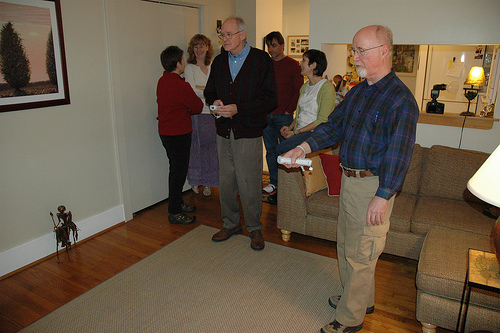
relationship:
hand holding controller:
[278, 144, 310, 174] [275, 158, 312, 168]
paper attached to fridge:
[445, 58, 465, 80] [421, 48, 483, 113]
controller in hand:
[277, 156, 314, 171] [273, 146, 308, 171]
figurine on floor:
[45, 202, 81, 267] [0, 172, 498, 328]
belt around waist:
[335, 163, 390, 177] [333, 152, 398, 196]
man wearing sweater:
[203, 16, 279, 250] [210, 59, 262, 101]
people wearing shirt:
[155, 45, 203, 224] [156, 71, 204, 136]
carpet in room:
[1, 219, 347, 331] [2, 0, 497, 332]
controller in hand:
[277, 156, 314, 171] [280, 147, 307, 169]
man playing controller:
[277, 24, 419, 333] [277, 156, 314, 171]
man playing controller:
[203, 16, 279, 250] [277, 156, 314, 171]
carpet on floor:
[18, 224, 342, 333] [1, 157, 418, 331]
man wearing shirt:
[203, 16, 279, 250] [225, 43, 249, 83]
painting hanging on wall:
[0, 0, 71, 113] [4, 2, 141, 282]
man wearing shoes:
[277, 24, 419, 333] [315, 292, 371, 330]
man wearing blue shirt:
[277, 24, 419, 333] [304, 68, 421, 201]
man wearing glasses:
[203, 16, 279, 250] [217, 27, 242, 40]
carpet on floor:
[18, 224, 342, 333] [0, 172, 498, 328]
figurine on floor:
[49, 204, 81, 263] [107, 223, 164, 268]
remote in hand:
[204, 95, 232, 130] [213, 104, 235, 124]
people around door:
[154, 44, 204, 226] [105, 0, 200, 217]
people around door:
[184, 32, 218, 196] [105, 0, 200, 217]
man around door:
[203, 16, 279, 250] [105, 0, 200, 217]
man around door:
[263, 31, 304, 194] [105, 0, 200, 217]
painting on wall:
[0, 2, 72, 114] [0, 2, 259, 278]